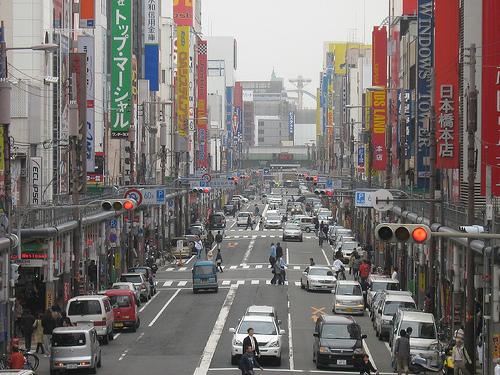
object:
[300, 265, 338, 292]
car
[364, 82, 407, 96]
streetlight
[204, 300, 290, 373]
street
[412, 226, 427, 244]
red light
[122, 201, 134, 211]
red light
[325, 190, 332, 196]
red light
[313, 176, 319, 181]
red light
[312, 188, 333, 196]
traffic light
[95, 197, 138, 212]
traffic light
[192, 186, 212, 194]
traffic light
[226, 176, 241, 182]
traffic light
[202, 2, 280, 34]
sky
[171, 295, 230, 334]
road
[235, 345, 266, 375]
civilian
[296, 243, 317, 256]
ground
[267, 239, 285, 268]
people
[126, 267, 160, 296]
car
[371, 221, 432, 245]
light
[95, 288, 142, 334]
car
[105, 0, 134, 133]
sign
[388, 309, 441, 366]
car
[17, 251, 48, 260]
sign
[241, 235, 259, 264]
traffic line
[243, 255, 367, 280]
street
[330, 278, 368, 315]
car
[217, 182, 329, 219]
street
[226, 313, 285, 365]
car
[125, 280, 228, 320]
street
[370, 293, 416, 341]
van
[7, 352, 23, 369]
red shirt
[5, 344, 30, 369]
pedestrian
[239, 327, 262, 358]
person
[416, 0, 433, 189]
blue sign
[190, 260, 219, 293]
minivan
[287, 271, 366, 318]
street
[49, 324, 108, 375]
vehicle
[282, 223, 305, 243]
vehicle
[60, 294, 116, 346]
vehicle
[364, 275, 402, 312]
vehicle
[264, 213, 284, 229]
vehicle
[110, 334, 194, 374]
road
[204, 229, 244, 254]
street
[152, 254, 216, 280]
street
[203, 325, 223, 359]
line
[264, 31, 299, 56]
white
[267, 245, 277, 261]
shirt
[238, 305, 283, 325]
car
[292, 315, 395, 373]
street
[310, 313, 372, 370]
car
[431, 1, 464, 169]
sign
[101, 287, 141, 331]
vehicle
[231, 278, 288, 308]
street